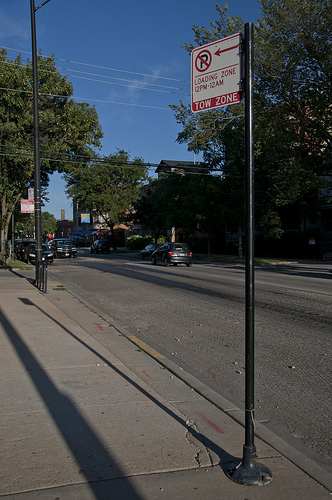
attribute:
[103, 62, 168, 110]
cloud — white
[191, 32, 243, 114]
sign — white, square, red and white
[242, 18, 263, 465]
pole — black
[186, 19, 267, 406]
post — black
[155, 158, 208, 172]
roof — sloped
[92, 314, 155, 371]
curb — yellow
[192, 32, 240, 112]
white sign — red and white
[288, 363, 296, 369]
stone — small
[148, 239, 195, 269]
car — dark blue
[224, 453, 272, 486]
base — metal, circular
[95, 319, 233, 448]
paint — red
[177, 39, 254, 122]
sign — red, white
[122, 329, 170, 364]
writing — yellow